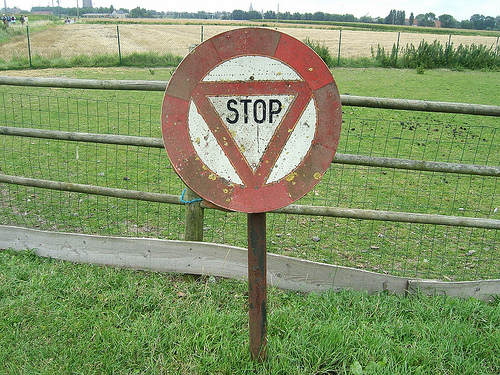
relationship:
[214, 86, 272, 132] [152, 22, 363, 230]
letters on sign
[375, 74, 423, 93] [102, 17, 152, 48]
grass on top of ground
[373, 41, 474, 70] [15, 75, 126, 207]
bushes near fence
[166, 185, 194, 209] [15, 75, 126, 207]
rope on fence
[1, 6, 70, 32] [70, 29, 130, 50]
people walking near field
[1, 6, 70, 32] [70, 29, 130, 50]
people standing in field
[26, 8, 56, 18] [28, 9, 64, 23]
roof of building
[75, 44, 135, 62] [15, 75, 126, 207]
weeds next to fence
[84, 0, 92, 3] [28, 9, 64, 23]
steeple on top of building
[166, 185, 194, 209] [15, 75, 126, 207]
rope aroudn fence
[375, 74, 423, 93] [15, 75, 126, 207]
grass under fence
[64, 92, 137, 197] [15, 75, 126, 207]
wire attached to fence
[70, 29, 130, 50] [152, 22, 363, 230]
field behind sign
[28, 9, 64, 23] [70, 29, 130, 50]
building across from field